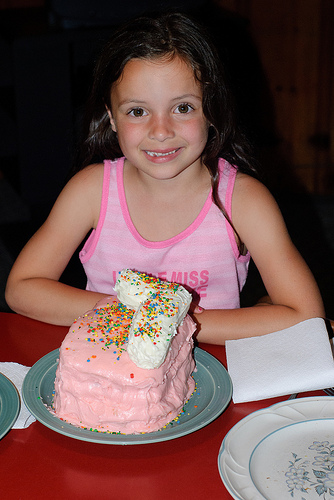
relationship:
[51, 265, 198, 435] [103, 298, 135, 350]
birthday cake topped with sprinkles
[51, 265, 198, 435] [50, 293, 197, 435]
birthday cake with pink frosting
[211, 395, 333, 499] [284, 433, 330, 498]
plate with flower decoration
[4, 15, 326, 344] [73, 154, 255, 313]
girl with a tank top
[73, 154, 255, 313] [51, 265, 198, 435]
tank top with a birthday cake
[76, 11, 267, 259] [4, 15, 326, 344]
dark hair on a girl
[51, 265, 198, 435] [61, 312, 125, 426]
birthday cake with pink frosting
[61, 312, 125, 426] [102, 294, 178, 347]
pink frosting and sprinkles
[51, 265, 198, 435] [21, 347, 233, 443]
birthday cake on plate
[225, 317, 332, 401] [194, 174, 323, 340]
napkin in of girl's arm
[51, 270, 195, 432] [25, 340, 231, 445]
frost on plate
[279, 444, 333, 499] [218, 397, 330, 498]
pattern on plate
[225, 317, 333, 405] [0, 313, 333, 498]
napkin on table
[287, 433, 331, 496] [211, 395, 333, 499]
design on plate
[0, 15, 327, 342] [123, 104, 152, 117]
girl has eye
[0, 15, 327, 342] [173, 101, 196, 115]
girl has eye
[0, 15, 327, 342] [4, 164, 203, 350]
girl has arm